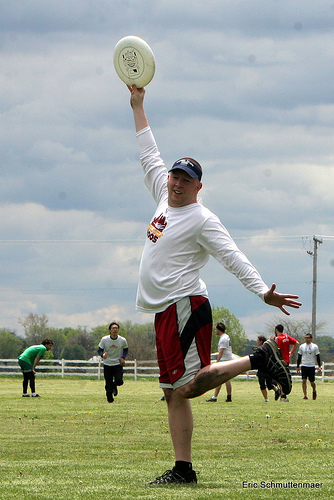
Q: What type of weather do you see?
A: It is cloudy.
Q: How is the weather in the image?
A: It is cloudy.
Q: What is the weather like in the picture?
A: It is cloudy.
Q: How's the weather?
A: It is cloudy.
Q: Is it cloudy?
A: Yes, it is cloudy.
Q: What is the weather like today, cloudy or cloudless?
A: It is cloudy.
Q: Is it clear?
A: No, it is cloudy.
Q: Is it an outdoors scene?
A: Yes, it is outdoors.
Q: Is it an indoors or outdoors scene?
A: It is outdoors.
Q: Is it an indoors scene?
A: No, it is outdoors.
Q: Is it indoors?
A: No, it is outdoors.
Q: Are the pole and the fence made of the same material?
A: Yes, both the pole and the fence are made of wood.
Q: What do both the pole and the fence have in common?
A: The material, both the pole and the fence are wooden.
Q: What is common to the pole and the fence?
A: The material, both the pole and the fence are wooden.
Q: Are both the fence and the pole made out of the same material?
A: Yes, both the fence and the pole are made of wood.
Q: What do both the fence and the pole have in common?
A: The material, both the fence and the pole are wooden.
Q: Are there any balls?
A: No, there are no balls.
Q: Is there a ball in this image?
A: No, there are no balls.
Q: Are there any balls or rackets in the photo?
A: No, there are no balls or rackets.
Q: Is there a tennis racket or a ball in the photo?
A: No, there are no balls or rackets.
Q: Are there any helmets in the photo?
A: No, there are no helmets.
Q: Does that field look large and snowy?
A: No, the field is large but grassy.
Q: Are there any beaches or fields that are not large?
A: No, there is a field but it is large.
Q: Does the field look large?
A: Yes, the field is large.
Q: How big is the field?
A: The field is large.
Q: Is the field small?
A: No, the field is large.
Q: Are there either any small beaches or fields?
A: No, there is a field but it is large.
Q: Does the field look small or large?
A: The field is large.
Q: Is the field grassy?
A: Yes, the field is grassy.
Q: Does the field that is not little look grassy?
A: Yes, the field is grassy.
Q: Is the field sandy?
A: No, the field is grassy.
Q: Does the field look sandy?
A: No, the field is grassy.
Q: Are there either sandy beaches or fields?
A: No, there is a field but it is grassy.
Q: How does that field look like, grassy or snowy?
A: The field is grassy.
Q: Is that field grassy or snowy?
A: The field is grassy.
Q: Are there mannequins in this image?
A: No, there are no mannequins.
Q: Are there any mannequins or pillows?
A: No, there are no mannequins or pillows.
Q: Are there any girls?
A: No, there are no girls.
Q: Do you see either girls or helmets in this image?
A: No, there are no girls or helmets.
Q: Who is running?
A: The man is running.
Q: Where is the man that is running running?
A: The man is running on the field.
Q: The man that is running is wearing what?
A: The man is wearing a shirt.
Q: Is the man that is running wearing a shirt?
A: Yes, the man is wearing a shirt.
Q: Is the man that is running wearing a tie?
A: No, the man is wearing a shirt.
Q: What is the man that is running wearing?
A: The man is wearing a shirt.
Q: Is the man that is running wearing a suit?
A: No, the man is wearing a shirt.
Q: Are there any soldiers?
A: No, there are no soldiers.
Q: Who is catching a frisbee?
A: The man is catching a frisbee.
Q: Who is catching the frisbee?
A: The man is catching a frisbee.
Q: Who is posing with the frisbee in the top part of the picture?
A: The man is posing with the frisbee.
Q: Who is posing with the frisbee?
A: The man is posing with the frisbee.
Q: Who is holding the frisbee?
A: The man is holding the frisbee.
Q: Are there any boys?
A: No, there are no boys.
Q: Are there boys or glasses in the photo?
A: No, there are no boys or glasses.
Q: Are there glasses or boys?
A: No, there are no boys or glasses.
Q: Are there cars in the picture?
A: No, there are no cars.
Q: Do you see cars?
A: No, there are no cars.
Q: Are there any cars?
A: No, there are no cars.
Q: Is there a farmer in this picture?
A: No, there are no farmers.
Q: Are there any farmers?
A: No, there are no farmers.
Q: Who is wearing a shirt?
A: The man is wearing a shirt.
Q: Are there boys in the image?
A: No, there are no boys.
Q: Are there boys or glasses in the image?
A: No, there are no boys or glasses.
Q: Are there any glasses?
A: No, there are no glasses.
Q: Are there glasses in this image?
A: No, there are no glasses.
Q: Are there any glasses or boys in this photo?
A: No, there are no glasses or boys.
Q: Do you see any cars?
A: No, there are no cars.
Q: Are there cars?
A: No, there are no cars.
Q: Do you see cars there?
A: No, there are no cars.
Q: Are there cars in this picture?
A: No, there are no cars.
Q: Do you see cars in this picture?
A: No, there are no cars.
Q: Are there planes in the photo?
A: No, there are no planes.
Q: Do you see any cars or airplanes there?
A: No, there are no airplanes or cars.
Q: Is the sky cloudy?
A: Yes, the sky is cloudy.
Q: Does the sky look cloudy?
A: Yes, the sky is cloudy.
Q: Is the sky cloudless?
A: No, the sky is cloudy.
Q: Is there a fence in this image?
A: Yes, there is a fence.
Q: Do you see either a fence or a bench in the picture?
A: Yes, there is a fence.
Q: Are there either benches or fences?
A: Yes, there is a fence.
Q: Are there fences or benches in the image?
A: Yes, there is a fence.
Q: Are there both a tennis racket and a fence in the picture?
A: No, there is a fence but no rackets.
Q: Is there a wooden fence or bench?
A: Yes, there is a wood fence.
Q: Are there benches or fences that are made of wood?
A: Yes, the fence is made of wood.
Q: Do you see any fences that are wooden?
A: Yes, there is a wood fence.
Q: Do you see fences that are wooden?
A: Yes, there is a fence that is wooden.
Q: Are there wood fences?
A: Yes, there is a fence that is made of wood.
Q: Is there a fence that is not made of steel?
A: Yes, there is a fence that is made of wood.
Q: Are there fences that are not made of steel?
A: Yes, there is a fence that is made of wood.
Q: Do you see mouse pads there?
A: No, there are no mouse pads.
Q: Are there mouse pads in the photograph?
A: No, there are no mouse pads.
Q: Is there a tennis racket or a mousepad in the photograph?
A: No, there are no mouse pads or rackets.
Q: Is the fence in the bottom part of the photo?
A: Yes, the fence is in the bottom of the image.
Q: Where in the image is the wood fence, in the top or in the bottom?
A: The fence is in the bottom of the image.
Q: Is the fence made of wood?
A: Yes, the fence is made of wood.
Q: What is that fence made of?
A: The fence is made of wood.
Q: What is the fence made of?
A: The fence is made of wood.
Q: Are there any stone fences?
A: No, there is a fence but it is made of wood.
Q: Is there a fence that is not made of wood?
A: No, there is a fence but it is made of wood.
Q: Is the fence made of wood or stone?
A: The fence is made of wood.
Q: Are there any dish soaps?
A: No, there are no dish soaps.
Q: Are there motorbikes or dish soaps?
A: No, there are no dish soaps or motorbikes.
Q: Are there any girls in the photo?
A: No, there are no girls.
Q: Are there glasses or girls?
A: No, there are no girls or glasses.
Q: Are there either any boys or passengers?
A: No, there are no boys or passengers.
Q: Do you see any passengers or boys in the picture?
A: No, there are no boys or passengers.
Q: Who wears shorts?
A: The man wears shorts.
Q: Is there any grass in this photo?
A: Yes, there is grass.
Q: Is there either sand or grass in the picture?
A: Yes, there is grass.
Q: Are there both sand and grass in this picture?
A: No, there is grass but no sand.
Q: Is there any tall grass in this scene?
A: Yes, there is tall grass.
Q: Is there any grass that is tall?
A: Yes, there is grass that is tall.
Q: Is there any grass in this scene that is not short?
A: Yes, there is tall grass.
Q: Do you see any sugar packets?
A: No, there are no sugar packets.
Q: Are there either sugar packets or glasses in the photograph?
A: No, there are no sugar packets or glasses.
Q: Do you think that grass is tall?
A: Yes, the grass is tall.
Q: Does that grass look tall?
A: Yes, the grass is tall.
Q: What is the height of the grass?
A: The grass is tall.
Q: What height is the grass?
A: The grass is tall.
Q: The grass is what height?
A: The grass is tall.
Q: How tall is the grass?
A: The grass is tall.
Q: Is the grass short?
A: No, the grass is tall.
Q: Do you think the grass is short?
A: No, the grass is tall.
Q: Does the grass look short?
A: No, the grass is tall.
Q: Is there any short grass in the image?
A: No, there is grass but it is tall.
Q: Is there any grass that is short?
A: No, there is grass but it is tall.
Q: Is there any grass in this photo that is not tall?
A: No, there is grass but it is tall.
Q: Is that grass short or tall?
A: The grass is tall.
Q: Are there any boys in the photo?
A: No, there are no boys.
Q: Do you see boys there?
A: No, there are no boys.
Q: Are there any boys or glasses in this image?
A: No, there are no boys or glasses.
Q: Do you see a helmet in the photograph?
A: No, there are no helmets.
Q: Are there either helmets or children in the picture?
A: No, there are no helmets or children.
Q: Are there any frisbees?
A: Yes, there is a frisbee.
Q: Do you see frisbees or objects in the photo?
A: Yes, there is a frisbee.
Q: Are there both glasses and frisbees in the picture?
A: No, there is a frisbee but no glasses.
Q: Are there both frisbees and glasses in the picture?
A: No, there is a frisbee but no glasses.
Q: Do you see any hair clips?
A: No, there are no hair clips.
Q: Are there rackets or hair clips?
A: No, there are no hair clips or rackets.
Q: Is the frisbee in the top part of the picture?
A: Yes, the frisbee is in the top of the image.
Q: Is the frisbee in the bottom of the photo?
A: No, the frisbee is in the top of the image.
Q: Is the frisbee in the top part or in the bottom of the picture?
A: The frisbee is in the top of the image.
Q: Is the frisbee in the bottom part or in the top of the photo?
A: The frisbee is in the top of the image.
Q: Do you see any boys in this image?
A: No, there are no boys.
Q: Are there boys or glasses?
A: No, there are no boys or glasses.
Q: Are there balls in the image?
A: No, there are no balls.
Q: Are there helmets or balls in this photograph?
A: No, there are no balls or helmets.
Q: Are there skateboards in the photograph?
A: No, there are no skateboards.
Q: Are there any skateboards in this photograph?
A: No, there are no skateboards.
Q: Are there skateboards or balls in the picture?
A: No, there are no skateboards or balls.